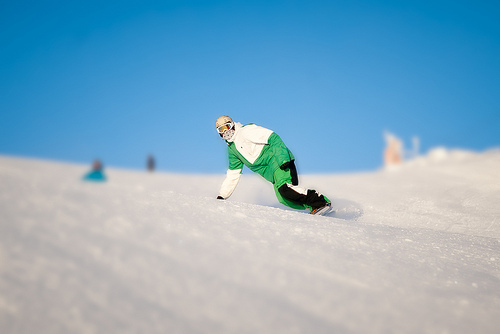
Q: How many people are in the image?
A: 2.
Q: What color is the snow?
A: White.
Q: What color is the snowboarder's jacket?
A: Green and white.